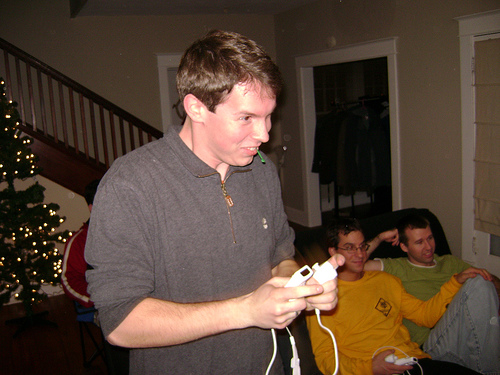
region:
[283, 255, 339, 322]
the man satanding is holding remote controls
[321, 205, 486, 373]
two people sitting on the couch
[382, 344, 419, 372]
the man in yellow shirt is holding a remote control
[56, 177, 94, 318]
the man at the back is wearing red jacket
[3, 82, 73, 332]
the christmas tree is near the stairs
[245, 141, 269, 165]
green toothpick on the man's mouth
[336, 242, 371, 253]
the man in yellow shirt is wearing eyeglasses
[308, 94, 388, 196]
jackets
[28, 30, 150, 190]
stairs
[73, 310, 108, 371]
chair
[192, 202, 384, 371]
a man is playing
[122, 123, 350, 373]
a man is playing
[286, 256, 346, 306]
wii remote controllers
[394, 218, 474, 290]
man wearing a greet t-shirt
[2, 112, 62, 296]
christmas tree int he background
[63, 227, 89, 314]
arm of a man wearing a red and white striped jacket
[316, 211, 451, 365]
two men sitting on a couch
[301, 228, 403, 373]
man wearing a yellow long sleeve shirt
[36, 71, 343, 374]
man playing with a wii controller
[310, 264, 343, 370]
wii nun-chuck connected to wii remote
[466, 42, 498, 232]
shades put on door.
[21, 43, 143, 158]
railing on the stairs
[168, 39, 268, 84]
Man has dark brown hair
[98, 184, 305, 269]
Man wears grey sweater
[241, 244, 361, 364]
Man holding Wii controller in hand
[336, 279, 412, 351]
Man wears yellow shirt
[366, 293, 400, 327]
Black symbol on yellow shirt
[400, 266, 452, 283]
Man wears green shirt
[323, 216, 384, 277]
Man has on glasses.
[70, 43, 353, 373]
Man is playing Wii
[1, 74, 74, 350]
Tall lit christmas tree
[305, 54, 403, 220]
Closet full of jackets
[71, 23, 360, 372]
a nerdy looking guy standing up playing a video game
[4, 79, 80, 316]
a Christmas tree with white lights next to a staircase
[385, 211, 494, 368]
a young man with a green shirt an jeans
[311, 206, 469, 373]
a young man with a yellow shirt and glasses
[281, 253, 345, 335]
the white video game controllers the man is holding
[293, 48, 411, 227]
a door way with a coat rack in it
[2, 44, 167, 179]
a dark brown wooden banister on a staircase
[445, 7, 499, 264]
the edge of a window with a cream colored shade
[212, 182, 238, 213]
a small zipper pull on the man's shirt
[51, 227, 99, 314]
the arm of a person wearing a red shirt with a white stripe